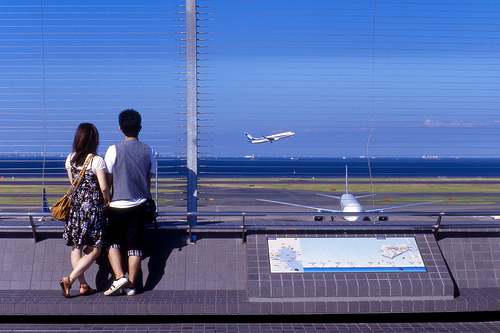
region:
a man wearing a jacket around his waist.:
[104, 87, 184, 301]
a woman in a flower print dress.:
[57, 114, 117, 302]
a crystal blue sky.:
[1, 0, 498, 157]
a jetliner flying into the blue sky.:
[232, 120, 306, 162]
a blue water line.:
[0, 154, 498, 176]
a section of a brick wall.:
[241, 227, 443, 325]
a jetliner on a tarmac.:
[244, 151, 456, 235]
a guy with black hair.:
[113, 110, 146, 148]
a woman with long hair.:
[66, 122, 111, 173]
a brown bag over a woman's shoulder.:
[37, 141, 98, 225]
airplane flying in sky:
[247, 128, 296, 144]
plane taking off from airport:
[245, 127, 295, 146]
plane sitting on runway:
[262, 162, 436, 219]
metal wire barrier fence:
[3, 3, 495, 217]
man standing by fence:
[108, 110, 156, 302]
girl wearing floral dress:
[63, 122, 106, 293]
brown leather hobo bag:
[49, 191, 71, 224]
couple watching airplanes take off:
[51, 110, 156, 302]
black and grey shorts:
[110, 203, 147, 258]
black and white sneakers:
[100, 276, 139, 298]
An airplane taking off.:
[241, 129, 299, 146]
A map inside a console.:
[265, 231, 427, 276]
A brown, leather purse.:
[47, 194, 72, 219]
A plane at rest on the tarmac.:
[252, 166, 447, 223]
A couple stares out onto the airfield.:
[55, 103, 160, 302]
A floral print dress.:
[73, 193, 101, 246]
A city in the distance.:
[0, 147, 42, 169]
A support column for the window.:
[171, 0, 214, 233]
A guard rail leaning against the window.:
[183, 209, 250, 239]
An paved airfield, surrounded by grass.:
[207, 174, 259, 209]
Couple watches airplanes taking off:
[54, 100, 156, 305]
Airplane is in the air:
[240, 127, 296, 148]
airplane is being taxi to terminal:
[255, 164, 442, 221]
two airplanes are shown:
[242, 129, 443, 218]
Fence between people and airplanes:
[1, 1, 498, 218]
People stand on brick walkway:
[3, 221, 498, 331]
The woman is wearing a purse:
[51, 148, 100, 222]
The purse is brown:
[49, 184, 74, 225]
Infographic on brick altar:
[263, 234, 429, 277]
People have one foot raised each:
[55, 242, 144, 301]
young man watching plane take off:
[101, 105, 178, 309]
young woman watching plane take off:
[61, 123, 109, 292]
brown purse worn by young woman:
[49, 192, 70, 226]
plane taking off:
[236, 117, 296, 159]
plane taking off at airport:
[237, 117, 301, 150]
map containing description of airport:
[244, 232, 434, 284]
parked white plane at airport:
[310, 182, 375, 221]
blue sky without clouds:
[6, 11, 156, 109]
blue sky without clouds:
[213, 11, 370, 112]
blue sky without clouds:
[339, 7, 489, 113]